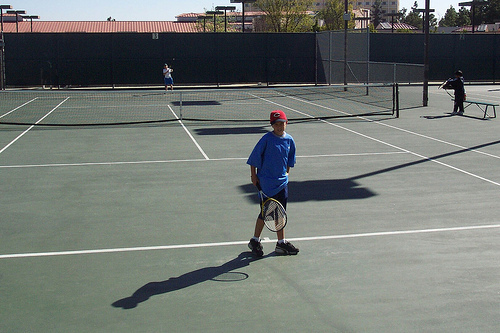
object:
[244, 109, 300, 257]
boy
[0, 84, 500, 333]
tennis court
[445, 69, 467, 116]
boy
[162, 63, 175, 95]
boy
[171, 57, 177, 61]
tennis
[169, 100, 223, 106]
shadow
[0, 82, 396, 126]
net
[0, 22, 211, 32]
roof top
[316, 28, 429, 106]
fence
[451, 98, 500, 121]
bench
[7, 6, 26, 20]
lighting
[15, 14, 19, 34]
post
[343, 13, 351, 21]
sign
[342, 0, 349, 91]
post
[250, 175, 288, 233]
tennis racket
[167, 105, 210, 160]
white line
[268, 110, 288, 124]
hat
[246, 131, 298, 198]
shirt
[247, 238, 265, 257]
shoes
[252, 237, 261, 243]
socks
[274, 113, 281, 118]
cardinal baseball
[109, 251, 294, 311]
shadow